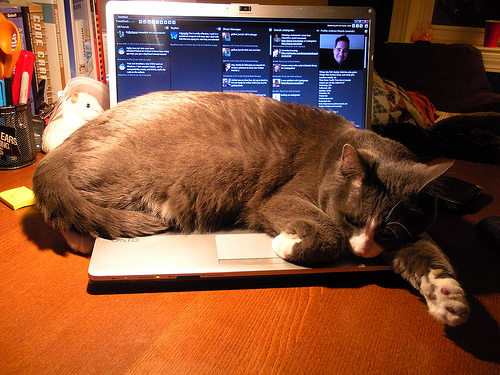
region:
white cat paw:
[413, 268, 475, 338]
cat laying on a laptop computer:
[23, 0, 493, 331]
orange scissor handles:
[0, 6, 21, 81]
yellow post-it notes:
[0, 182, 40, 212]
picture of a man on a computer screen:
[302, 17, 368, 98]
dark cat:
[27, 87, 476, 330]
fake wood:
[48, 296, 348, 373]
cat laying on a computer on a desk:
[2, 1, 497, 372]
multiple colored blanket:
[370, 71, 447, 133]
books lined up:
[0, 1, 113, 129]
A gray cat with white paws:
[35, 96, 483, 320]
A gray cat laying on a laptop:
[46, 1, 463, 297]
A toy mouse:
[36, 92, 101, 153]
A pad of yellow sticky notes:
[2, 179, 37, 213]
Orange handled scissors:
[0, 15, 21, 108]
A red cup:
[481, 12, 498, 47]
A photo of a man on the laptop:
[104, 8, 383, 122]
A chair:
[373, 32, 498, 162]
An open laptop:
[103, 4, 391, 301]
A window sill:
[392, 11, 499, 65]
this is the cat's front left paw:
[415, 260, 477, 340]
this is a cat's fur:
[100, 126, 182, 163]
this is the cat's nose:
[348, 237, 369, 262]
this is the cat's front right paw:
[263, 207, 318, 264]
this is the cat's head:
[331, 126, 442, 277]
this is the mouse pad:
[205, 225, 321, 290]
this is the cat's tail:
[36, 135, 175, 251]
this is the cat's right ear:
[326, 133, 385, 183]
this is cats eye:
[329, 186, 376, 248]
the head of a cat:
[313, 142, 460, 259]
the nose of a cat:
[351, 244, 371, 255]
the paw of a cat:
[413, 267, 473, 333]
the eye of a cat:
[341, 211, 363, 228]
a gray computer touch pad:
[208, 227, 280, 264]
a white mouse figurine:
[37, 87, 107, 162]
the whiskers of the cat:
[381, 192, 419, 238]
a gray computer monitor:
[102, 2, 375, 141]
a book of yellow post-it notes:
[0, 182, 43, 211]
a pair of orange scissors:
[0, 12, 26, 79]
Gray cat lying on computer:
[46, 91, 492, 327]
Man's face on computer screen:
[317, 31, 362, 66]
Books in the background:
[2, 2, 109, 84]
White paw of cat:
[420, 272, 470, 327]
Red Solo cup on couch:
[485, 15, 496, 40]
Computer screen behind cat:
[115, 11, 366, 111]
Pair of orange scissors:
[0, 10, 11, 80]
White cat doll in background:
[55, 86, 100, 127]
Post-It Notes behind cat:
[0, 185, 35, 205]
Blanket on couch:
[373, 66, 440, 129]